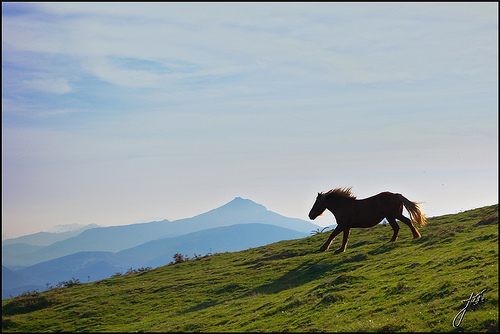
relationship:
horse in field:
[307, 184, 422, 256] [4, 197, 495, 333]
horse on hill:
[307, 184, 422, 256] [3, 198, 497, 333]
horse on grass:
[307, 184, 422, 256] [6, 197, 499, 334]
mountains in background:
[1, 195, 327, 302] [10, 75, 496, 260]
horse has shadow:
[307, 184, 422, 256] [170, 247, 363, 314]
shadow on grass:
[170, 247, 363, 314] [6, 197, 499, 334]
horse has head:
[307, 184, 422, 256] [306, 189, 329, 222]